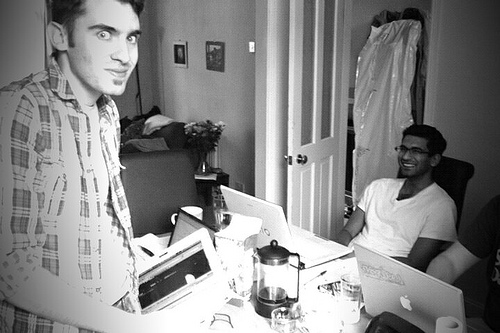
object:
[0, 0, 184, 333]
man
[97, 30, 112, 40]
eye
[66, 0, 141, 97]
face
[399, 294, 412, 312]
apple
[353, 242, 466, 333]
computer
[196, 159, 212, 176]
vase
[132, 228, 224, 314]
press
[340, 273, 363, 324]
cup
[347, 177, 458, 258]
shirt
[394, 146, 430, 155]
glasses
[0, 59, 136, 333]
shirt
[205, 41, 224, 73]
picture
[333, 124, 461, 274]
men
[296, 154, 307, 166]
knob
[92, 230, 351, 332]
table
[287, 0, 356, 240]
door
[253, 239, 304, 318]
lantern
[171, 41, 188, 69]
photograph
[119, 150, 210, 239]
bed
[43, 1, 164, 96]
head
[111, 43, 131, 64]
nose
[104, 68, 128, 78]
lip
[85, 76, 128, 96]
chin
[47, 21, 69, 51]
ear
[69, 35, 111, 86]
cheek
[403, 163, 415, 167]
teeth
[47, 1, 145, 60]
hair